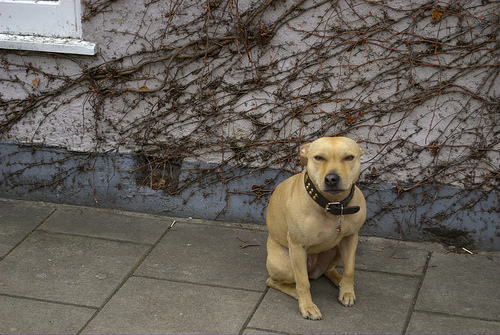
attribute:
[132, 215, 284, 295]
tile — cement 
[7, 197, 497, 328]
tile — cement 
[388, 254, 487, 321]
sidewalk — cement 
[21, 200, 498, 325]
sidewalk — cement, tiled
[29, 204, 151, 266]
tile — cement 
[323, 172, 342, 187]
nose — black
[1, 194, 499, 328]
sidewalk — tiled, cement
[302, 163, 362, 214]
collar — brown